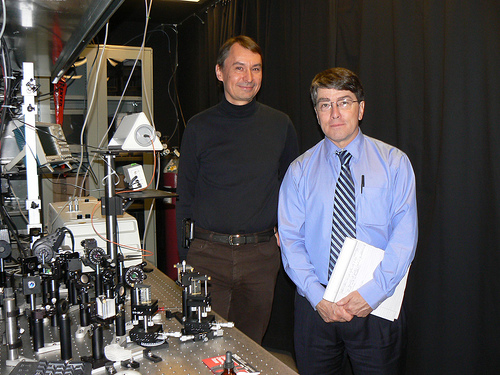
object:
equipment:
[1, 0, 254, 371]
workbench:
[3, 255, 300, 374]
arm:
[375, 152, 418, 294]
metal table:
[0, 258, 298, 373]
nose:
[330, 105, 342, 119]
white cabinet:
[89, 42, 158, 125]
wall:
[98, 0, 219, 120]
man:
[277, 64, 419, 374]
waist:
[294, 245, 409, 298]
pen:
[358, 174, 365, 191]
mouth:
[323, 123, 351, 129]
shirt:
[275, 127, 420, 311]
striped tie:
[328, 148, 360, 278]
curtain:
[218, 0, 500, 371]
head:
[307, 66, 369, 139]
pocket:
[356, 187, 386, 228]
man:
[171, 35, 307, 348]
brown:
[186, 232, 282, 346]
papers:
[321, 237, 409, 322]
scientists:
[182, 37, 422, 375]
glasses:
[314, 99, 361, 109]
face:
[309, 66, 366, 145]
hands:
[313, 288, 370, 324]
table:
[126, 256, 297, 373]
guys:
[167, 32, 427, 374]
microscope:
[171, 257, 230, 346]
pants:
[286, 305, 408, 374]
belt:
[183, 224, 279, 248]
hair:
[310, 67, 363, 107]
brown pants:
[185, 237, 282, 355]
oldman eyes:
[319, 100, 353, 110]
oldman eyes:
[233, 66, 260, 71]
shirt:
[173, 103, 303, 269]